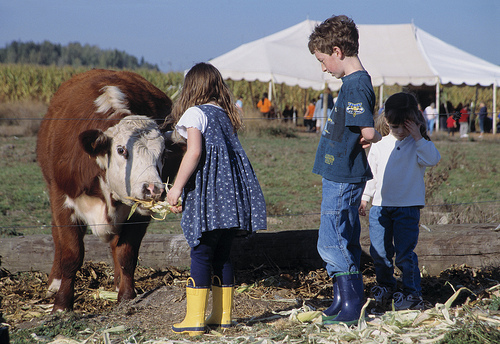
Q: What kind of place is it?
A: It is a farm.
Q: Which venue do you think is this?
A: This is a farm.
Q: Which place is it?
A: It is a farm.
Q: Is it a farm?
A: Yes, it is a farm.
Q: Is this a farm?
A: Yes, it is a farm.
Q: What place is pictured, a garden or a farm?
A: It is a farm.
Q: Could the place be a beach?
A: No, it is a farm.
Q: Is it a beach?
A: No, it is a farm.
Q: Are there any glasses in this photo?
A: No, there are no glasses.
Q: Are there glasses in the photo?
A: No, there are no glasses.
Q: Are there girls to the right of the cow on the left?
A: Yes, there is a girl to the right of the cow.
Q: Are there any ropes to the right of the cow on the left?
A: No, there is a girl to the right of the cow.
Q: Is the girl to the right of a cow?
A: Yes, the girl is to the right of a cow.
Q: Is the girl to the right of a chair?
A: No, the girl is to the right of a cow.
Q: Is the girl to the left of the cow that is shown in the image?
A: No, the girl is to the right of the cow.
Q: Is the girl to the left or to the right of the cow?
A: The girl is to the right of the cow.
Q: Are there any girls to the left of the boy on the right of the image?
A: Yes, there is a girl to the left of the boy.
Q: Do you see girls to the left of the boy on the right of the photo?
A: Yes, there is a girl to the left of the boy.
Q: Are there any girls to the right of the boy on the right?
A: No, the girl is to the left of the boy.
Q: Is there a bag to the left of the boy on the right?
A: No, there is a girl to the left of the boy.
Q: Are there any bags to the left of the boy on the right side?
A: No, there is a girl to the left of the boy.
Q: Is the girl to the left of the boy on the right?
A: Yes, the girl is to the left of the boy.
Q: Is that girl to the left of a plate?
A: No, the girl is to the left of the boy.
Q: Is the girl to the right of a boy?
A: No, the girl is to the left of a boy.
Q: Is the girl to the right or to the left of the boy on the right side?
A: The girl is to the left of the boy.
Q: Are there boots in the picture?
A: Yes, there are boots.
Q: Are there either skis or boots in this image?
A: Yes, there are boots.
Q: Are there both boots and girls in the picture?
A: Yes, there are both boots and a girl.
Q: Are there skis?
A: No, there are no skis.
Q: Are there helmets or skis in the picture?
A: No, there are no skis or helmets.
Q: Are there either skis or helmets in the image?
A: No, there are no skis or helmets.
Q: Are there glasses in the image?
A: No, there are no glasses.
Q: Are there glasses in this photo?
A: No, there are no glasses.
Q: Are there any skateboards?
A: No, there are no skateboards.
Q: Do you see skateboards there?
A: No, there are no skateboards.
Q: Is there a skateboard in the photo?
A: No, there are no skateboards.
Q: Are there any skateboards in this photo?
A: No, there are no skateboards.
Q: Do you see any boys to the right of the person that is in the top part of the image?
A: Yes, there is a boy to the right of the person.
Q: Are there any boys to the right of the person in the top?
A: Yes, there is a boy to the right of the person.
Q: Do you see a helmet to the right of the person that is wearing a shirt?
A: No, there is a boy to the right of the person.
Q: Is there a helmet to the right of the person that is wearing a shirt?
A: No, there is a boy to the right of the person.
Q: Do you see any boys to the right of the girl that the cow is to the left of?
A: Yes, there is a boy to the right of the girl.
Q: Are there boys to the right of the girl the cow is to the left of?
A: Yes, there is a boy to the right of the girl.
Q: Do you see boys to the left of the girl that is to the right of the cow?
A: No, the boy is to the right of the girl.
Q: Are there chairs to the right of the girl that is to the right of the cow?
A: No, there is a boy to the right of the girl.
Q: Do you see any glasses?
A: No, there are no glasses.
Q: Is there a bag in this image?
A: No, there are no bags.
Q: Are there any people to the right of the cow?
A: Yes, there is a person to the right of the cow.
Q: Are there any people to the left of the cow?
A: No, the person is to the right of the cow.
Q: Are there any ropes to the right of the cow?
A: No, there is a person to the right of the cow.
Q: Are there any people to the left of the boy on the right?
A: Yes, there is a person to the left of the boy.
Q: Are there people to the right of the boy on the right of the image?
A: No, the person is to the left of the boy.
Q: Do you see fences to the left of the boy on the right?
A: No, there is a person to the left of the boy.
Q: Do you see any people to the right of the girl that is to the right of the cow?
A: Yes, there is a person to the right of the girl.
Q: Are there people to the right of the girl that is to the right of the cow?
A: Yes, there is a person to the right of the girl.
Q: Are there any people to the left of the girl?
A: No, the person is to the right of the girl.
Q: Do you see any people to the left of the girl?
A: No, the person is to the right of the girl.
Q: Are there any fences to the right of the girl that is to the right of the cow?
A: No, there is a person to the right of the girl.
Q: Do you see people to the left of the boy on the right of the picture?
A: Yes, there is a person to the left of the boy.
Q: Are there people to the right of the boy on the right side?
A: No, the person is to the left of the boy.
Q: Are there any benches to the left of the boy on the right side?
A: No, there is a person to the left of the boy.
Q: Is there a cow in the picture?
A: Yes, there is a cow.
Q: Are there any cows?
A: Yes, there is a cow.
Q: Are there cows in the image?
A: Yes, there is a cow.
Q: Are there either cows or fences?
A: Yes, there is a cow.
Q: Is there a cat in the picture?
A: No, there are no cats.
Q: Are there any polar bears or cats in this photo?
A: No, there are no cats or polar bears.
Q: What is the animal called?
A: The animal is a cow.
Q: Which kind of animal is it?
A: The animal is a cow.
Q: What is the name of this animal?
A: This is a cow.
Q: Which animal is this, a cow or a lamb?
A: This is a cow.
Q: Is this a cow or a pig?
A: This is a cow.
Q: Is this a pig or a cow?
A: This is a cow.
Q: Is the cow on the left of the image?
A: Yes, the cow is on the left of the image.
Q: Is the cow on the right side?
A: No, the cow is on the left of the image.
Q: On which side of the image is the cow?
A: The cow is on the left of the image.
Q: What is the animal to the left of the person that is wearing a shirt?
A: The animal is a cow.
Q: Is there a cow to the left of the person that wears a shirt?
A: Yes, there is a cow to the left of the person.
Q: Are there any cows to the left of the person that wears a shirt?
A: Yes, there is a cow to the left of the person.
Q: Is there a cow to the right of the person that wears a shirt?
A: No, the cow is to the left of the person.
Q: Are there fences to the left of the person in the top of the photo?
A: No, there is a cow to the left of the person.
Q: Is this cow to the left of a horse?
A: No, the cow is to the left of a person.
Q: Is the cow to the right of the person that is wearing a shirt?
A: No, the cow is to the left of the person.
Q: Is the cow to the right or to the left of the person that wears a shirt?
A: The cow is to the left of the person.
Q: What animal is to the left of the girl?
A: The animal is a cow.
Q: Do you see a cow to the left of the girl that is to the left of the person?
A: Yes, there is a cow to the left of the girl.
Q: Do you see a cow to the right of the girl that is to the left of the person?
A: No, the cow is to the left of the girl.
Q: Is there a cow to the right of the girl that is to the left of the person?
A: No, the cow is to the left of the girl.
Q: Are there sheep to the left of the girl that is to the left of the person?
A: No, there is a cow to the left of the girl.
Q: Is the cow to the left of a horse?
A: No, the cow is to the left of the girl.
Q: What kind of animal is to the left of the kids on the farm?
A: The animal is a cow.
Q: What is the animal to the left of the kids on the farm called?
A: The animal is a cow.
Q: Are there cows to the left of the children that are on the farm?
A: Yes, there is a cow to the left of the kids.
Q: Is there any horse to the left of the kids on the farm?
A: No, there is a cow to the left of the children.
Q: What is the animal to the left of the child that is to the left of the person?
A: The animal is a cow.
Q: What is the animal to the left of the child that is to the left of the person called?
A: The animal is a cow.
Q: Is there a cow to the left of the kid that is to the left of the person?
A: Yes, there is a cow to the left of the kid.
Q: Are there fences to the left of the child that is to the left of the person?
A: No, there is a cow to the left of the child.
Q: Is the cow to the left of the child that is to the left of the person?
A: Yes, the cow is to the left of the child.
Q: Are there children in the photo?
A: Yes, there are children.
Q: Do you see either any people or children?
A: Yes, there are children.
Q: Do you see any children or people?
A: Yes, there are children.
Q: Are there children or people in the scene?
A: Yes, there are children.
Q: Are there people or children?
A: Yes, there are children.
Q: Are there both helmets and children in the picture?
A: No, there are children but no helmets.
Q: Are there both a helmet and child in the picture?
A: No, there are children but no helmets.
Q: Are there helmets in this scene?
A: No, there are no helmets.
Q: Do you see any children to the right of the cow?
A: Yes, there are children to the right of the cow.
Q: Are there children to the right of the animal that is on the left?
A: Yes, there are children to the right of the cow.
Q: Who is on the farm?
A: The kids are on the farm.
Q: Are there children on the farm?
A: Yes, there are children on the farm.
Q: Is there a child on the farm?
A: Yes, there are children on the farm.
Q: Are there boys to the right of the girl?
A: Yes, there is a boy to the right of the girl.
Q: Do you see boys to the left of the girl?
A: No, the boy is to the right of the girl.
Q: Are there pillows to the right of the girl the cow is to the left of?
A: No, there is a boy to the right of the girl.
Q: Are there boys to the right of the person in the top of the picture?
A: Yes, there is a boy to the right of the person.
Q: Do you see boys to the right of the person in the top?
A: Yes, there is a boy to the right of the person.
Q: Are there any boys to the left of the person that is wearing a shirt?
A: No, the boy is to the right of the person.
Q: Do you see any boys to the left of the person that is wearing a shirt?
A: No, the boy is to the right of the person.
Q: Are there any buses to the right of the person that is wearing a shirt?
A: No, there is a boy to the right of the person.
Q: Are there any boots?
A: Yes, there are boots.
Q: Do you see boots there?
A: Yes, there are boots.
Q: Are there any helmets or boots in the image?
A: Yes, there are boots.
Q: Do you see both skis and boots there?
A: No, there are boots but no skis.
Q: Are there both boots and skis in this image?
A: No, there are boots but no skis.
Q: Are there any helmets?
A: No, there are no helmets.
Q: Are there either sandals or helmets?
A: No, there are no helmets or sandals.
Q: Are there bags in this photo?
A: No, there are no bags.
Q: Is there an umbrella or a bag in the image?
A: No, there are no bags or umbrellas.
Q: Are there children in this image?
A: Yes, there is a child.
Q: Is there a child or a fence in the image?
A: Yes, there is a child.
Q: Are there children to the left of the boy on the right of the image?
A: Yes, there is a child to the left of the boy.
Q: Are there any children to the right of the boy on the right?
A: No, the child is to the left of the boy.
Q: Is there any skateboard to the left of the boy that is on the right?
A: No, there is a child to the left of the boy.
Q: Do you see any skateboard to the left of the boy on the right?
A: No, there is a child to the left of the boy.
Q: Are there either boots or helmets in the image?
A: Yes, there are boots.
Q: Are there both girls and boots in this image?
A: Yes, there are both boots and a girl.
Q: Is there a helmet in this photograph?
A: No, there are no helmets.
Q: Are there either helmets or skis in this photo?
A: No, there are no helmets or skis.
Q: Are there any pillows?
A: No, there are no pillows.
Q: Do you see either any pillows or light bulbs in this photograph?
A: No, there are no pillows or light bulbs.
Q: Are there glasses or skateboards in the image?
A: No, there are no skateboards or glasses.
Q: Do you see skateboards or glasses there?
A: No, there are no skateboards or glasses.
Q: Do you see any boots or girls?
A: Yes, there are boots.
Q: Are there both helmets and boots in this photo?
A: No, there are boots but no helmets.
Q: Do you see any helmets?
A: No, there are no helmets.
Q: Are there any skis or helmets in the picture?
A: No, there are no helmets or skis.